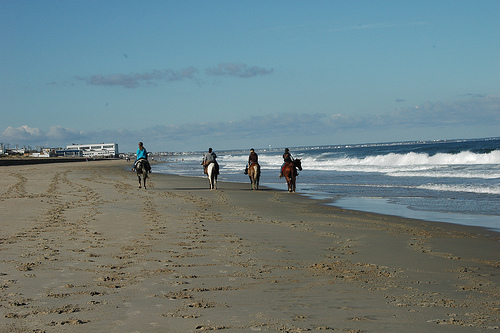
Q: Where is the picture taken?
A: The beach.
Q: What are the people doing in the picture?
A: Riding.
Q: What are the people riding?
A: Horses.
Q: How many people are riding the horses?
A: 4.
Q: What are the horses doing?
A: Walking.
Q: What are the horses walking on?
A: Sand.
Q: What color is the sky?
A: Blue.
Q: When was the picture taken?
A: Daytime.